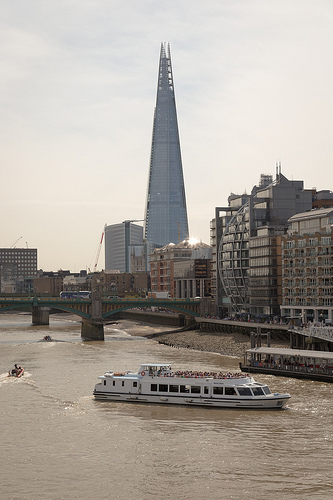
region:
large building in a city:
[131, 33, 199, 242]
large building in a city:
[96, 218, 147, 276]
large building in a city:
[241, 219, 289, 322]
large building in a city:
[274, 208, 332, 324]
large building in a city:
[213, 179, 320, 321]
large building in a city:
[143, 237, 212, 303]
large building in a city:
[169, 254, 215, 304]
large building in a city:
[86, 267, 151, 295]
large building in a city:
[0, 245, 41, 283]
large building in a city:
[58, 272, 88, 298]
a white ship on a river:
[92, 362, 291, 408]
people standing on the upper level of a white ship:
[145, 364, 250, 378]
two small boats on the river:
[6, 334, 54, 379]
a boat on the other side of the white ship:
[238, 344, 331, 382]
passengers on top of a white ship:
[148, 365, 250, 379]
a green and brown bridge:
[0, 294, 195, 321]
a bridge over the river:
[0, 296, 205, 341]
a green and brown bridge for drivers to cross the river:
[0, 296, 199, 341]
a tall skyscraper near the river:
[142, 40, 188, 237]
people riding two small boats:
[0, 333, 79, 384]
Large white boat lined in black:
[89, 363, 292, 431]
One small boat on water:
[4, 353, 30, 390]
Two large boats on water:
[92, 336, 323, 408]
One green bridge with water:
[6, 287, 215, 325]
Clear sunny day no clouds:
[45, 216, 82, 251]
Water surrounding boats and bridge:
[0, 338, 327, 466]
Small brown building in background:
[2, 239, 51, 303]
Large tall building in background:
[130, 36, 198, 255]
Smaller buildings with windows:
[104, 189, 332, 331]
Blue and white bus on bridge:
[58, 287, 96, 304]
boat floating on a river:
[93, 365, 292, 410]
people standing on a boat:
[166, 369, 247, 377]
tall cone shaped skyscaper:
[144, 39, 187, 252]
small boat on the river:
[9, 363, 24, 379]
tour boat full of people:
[238, 345, 332, 381]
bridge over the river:
[1, 295, 215, 342]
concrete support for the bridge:
[82, 320, 104, 341]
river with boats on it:
[0, 312, 331, 498]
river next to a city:
[0, 311, 332, 497]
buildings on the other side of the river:
[1, 41, 332, 322]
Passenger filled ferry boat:
[88, 361, 297, 417]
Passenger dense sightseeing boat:
[90, 363, 290, 414]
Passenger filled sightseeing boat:
[90, 362, 288, 413]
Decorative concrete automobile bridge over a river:
[5, 287, 169, 347]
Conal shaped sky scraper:
[145, 37, 194, 241]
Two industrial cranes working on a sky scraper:
[91, 216, 141, 269]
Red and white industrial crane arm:
[92, 230, 103, 271]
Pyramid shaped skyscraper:
[142, 35, 195, 241]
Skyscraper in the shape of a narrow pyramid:
[149, 37, 191, 242]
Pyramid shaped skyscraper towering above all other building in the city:
[139, 33, 313, 244]